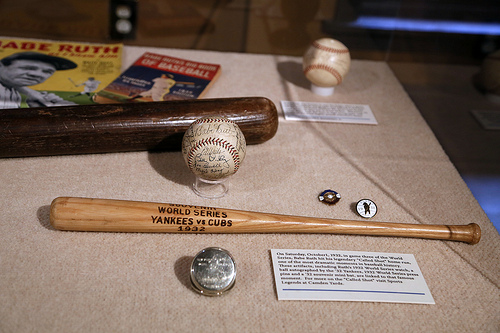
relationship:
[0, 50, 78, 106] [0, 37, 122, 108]
babe ruth on a book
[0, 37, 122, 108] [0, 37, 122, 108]
book has a book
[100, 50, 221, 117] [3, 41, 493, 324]
book on a table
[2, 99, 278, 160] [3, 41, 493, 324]
baseball bat on a table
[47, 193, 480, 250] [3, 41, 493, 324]
baseball bat sitting on a table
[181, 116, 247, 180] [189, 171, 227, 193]
ball on a stand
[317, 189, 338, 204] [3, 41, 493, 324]
baseball pin on a table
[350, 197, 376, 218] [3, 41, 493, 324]
baseball pin on a table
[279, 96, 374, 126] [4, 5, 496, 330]
information card in a display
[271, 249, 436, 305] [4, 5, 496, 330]
card in a display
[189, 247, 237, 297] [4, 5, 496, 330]
coin in a display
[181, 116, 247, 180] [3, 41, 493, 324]
ball on top of a table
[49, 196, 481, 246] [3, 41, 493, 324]
baseball bat on top of a table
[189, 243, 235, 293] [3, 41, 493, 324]
coin on top of a table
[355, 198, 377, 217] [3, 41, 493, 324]
baseball pin on top of a table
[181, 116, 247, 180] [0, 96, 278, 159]
ball in between a baseball bat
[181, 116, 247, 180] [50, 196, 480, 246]
ball in between a bat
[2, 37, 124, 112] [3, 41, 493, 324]
book on top of a table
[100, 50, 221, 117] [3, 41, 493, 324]
book on top of a table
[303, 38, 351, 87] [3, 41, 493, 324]
ball on top of a table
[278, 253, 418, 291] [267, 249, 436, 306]
writing on a card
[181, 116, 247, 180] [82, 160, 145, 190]
ball on table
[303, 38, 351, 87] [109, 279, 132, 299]
ball on table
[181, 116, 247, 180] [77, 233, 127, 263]
ball on table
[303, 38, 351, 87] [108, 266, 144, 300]
ball on table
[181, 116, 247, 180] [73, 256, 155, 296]
ball on table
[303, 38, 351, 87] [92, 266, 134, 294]
ball on table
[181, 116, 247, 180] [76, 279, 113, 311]
ball on table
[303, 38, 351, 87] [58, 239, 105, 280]
ball on table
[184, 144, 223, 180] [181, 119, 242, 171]
writing on baseball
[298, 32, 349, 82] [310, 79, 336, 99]
ball on base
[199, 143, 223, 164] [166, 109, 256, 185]
autographs on ball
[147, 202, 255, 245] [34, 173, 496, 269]
words on bat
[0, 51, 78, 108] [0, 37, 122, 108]
babe ruth on book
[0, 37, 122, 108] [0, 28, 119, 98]
book of book